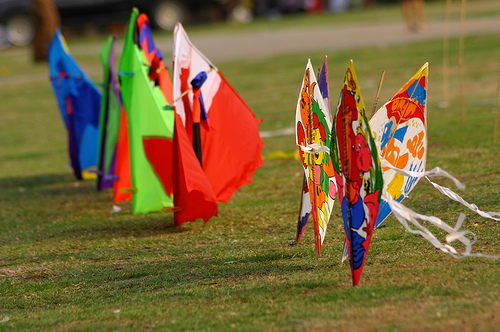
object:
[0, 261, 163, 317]
part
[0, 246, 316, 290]
shade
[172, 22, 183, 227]
edge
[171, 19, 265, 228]
flag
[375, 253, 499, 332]
part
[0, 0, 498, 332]
ground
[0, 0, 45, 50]
part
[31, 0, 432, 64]
stand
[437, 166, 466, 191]
part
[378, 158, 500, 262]
ribbon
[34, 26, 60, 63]
part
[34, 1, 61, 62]
stick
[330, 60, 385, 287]
kite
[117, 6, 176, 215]
kite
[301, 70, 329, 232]
kid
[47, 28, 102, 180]
kite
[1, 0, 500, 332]
grass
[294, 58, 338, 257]
kite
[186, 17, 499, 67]
pavement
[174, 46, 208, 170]
drawings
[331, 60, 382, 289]
colors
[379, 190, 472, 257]
string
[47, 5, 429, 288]
line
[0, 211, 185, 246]
shadow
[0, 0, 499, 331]
picture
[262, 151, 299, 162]
tail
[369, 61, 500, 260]
kite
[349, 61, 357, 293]
stick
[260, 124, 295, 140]
line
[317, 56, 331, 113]
connector